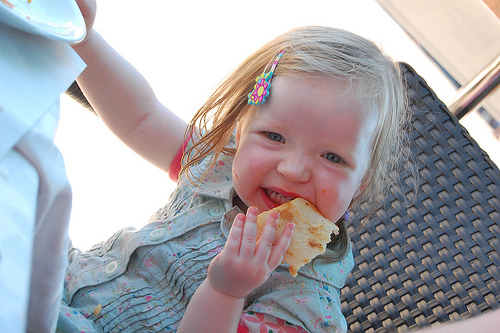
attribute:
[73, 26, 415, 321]
girl — toddler, smiling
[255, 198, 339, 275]
food — pizza, bread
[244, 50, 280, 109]
flower band — colorful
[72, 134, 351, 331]
blouse — light blue, decorated, gray, floral, blue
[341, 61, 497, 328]
chair — reclining, woven, plastic, black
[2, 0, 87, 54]
plate — light blue, empty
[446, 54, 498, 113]
pole — silver, metal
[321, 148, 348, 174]
eye — blue